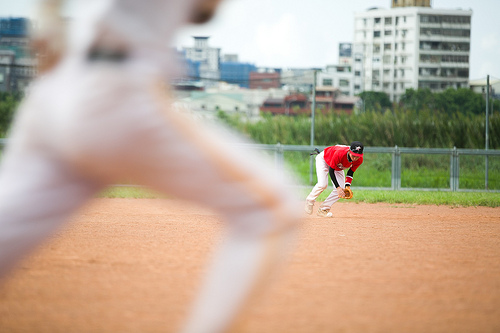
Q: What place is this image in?
A: It is at the field.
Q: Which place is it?
A: It is a field.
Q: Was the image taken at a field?
A: Yes, it was taken in a field.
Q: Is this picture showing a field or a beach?
A: It is showing a field.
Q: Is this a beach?
A: No, it is a field.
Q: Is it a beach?
A: No, it is a field.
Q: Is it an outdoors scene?
A: Yes, it is outdoors.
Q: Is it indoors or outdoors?
A: It is outdoors.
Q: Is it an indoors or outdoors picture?
A: It is outdoors.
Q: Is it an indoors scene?
A: No, it is outdoors.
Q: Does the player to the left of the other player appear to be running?
A: Yes, the player is running.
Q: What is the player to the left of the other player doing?
A: The player is running.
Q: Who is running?
A: The player is running.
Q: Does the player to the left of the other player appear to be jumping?
A: No, the player is running.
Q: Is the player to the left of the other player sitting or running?
A: The player is running.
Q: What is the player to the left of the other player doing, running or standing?
A: The player is running.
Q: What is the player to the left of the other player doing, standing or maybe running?
A: The player is running.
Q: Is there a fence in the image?
A: Yes, there is a fence.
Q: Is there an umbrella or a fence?
A: Yes, there is a fence.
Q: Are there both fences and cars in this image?
A: No, there is a fence but no cars.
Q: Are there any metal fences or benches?
A: Yes, there is a metal fence.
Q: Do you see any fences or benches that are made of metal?
A: Yes, the fence is made of metal.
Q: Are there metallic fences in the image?
A: Yes, there is a metal fence.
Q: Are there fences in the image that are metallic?
A: Yes, there is a fence that is metallic.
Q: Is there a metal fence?
A: Yes, there is a fence that is made of metal.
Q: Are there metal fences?
A: Yes, there is a fence that is made of metal.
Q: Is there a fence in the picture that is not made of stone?
A: Yes, there is a fence that is made of metal.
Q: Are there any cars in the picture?
A: No, there are no cars.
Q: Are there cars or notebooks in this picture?
A: No, there are no cars or notebooks.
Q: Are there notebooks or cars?
A: No, there are no cars or notebooks.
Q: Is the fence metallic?
A: Yes, the fence is metallic.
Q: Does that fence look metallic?
A: Yes, the fence is metallic.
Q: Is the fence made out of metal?
A: Yes, the fence is made of metal.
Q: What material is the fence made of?
A: The fence is made of metal.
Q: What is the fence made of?
A: The fence is made of metal.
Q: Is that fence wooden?
A: No, the fence is metallic.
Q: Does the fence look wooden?
A: No, the fence is metallic.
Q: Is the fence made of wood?
A: No, the fence is made of metal.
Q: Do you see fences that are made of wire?
A: No, there is a fence but it is made of metal.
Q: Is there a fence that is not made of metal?
A: No, there is a fence but it is made of metal.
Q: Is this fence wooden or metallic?
A: The fence is metallic.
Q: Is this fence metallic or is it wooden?
A: The fence is metallic.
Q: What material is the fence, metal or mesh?
A: The fence is made of metal.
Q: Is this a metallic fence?
A: Yes, this is a metallic fence.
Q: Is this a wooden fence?
A: No, this is a metallic fence.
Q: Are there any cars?
A: No, there are no cars.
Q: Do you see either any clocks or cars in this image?
A: No, there are no cars or clocks.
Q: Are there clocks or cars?
A: No, there are no cars or clocks.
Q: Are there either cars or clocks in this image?
A: No, there are no cars or clocks.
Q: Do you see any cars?
A: No, there are no cars.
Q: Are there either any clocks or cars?
A: No, there are no cars or clocks.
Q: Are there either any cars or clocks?
A: No, there are no cars or clocks.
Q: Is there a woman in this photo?
A: No, there are no women.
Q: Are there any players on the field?
A: Yes, there is a player on the field.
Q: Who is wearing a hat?
A: The player is wearing a hat.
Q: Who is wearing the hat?
A: The player is wearing a hat.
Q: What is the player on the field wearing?
A: The player is wearing a hat.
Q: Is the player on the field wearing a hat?
A: Yes, the player is wearing a hat.